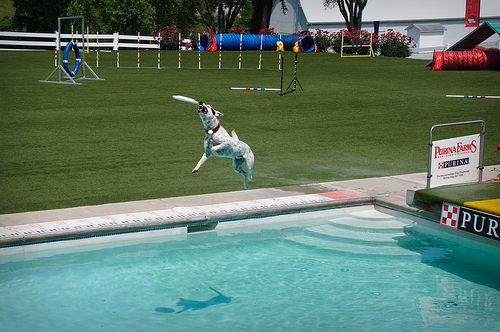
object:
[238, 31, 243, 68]
pole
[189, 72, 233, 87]
ground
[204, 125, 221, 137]
red necklace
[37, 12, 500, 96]
obstacle course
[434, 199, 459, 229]
sign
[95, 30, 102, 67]
pole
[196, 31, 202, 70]
pole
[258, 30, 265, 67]
pole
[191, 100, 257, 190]
dog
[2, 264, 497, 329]
water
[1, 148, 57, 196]
green grass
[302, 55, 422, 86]
field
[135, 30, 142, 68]
pole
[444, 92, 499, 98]
pole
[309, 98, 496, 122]
ground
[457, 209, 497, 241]
white letters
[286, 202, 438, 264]
steps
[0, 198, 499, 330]
pool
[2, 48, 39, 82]
ground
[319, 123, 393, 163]
ground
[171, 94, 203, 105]
frisbee